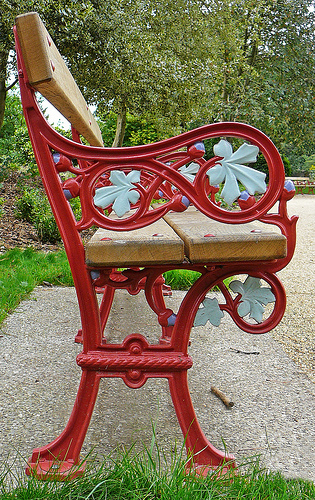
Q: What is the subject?
A: A bench.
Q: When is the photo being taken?
A: Day time.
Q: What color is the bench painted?
A: Red.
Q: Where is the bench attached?
A: To the pavement.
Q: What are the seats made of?
A: Wood.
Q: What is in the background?
A: Trees.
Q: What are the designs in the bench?
A: Leaves and berries.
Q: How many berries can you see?
A: Nine.